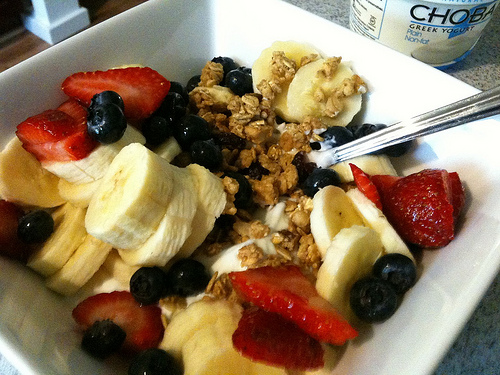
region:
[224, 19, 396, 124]
bananas with granola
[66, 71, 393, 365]
fruit plate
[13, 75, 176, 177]
strawberries bananas and blueberries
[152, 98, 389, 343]
fruit salad with cream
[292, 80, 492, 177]
hardware inside a fruit plate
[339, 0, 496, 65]
cup of yogart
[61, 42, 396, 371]
fruit plate with bananas and yogurt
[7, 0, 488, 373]
fruit salad in a to go box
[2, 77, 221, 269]
cut bananas strawberries and blueberries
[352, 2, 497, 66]
greek yugurt cup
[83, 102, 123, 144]
a blueberry in the bowl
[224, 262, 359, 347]
a strawberry slice in the bowl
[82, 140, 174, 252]
a banana slice in the bowl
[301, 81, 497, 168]
a metal eating utensil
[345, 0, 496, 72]
a cup of yogurt next to the bowl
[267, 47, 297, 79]
a cluster of brown granola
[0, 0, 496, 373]
a white bowl filled with fruit and granola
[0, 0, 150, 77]
a brown wooden floog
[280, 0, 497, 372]
a gray tile table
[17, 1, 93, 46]
a white pillar on the floor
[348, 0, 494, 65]
a container of yogurt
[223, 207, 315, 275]
granola and yogurt mixed together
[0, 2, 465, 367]
a white bowl for food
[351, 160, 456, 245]
slices of strawberries in the corner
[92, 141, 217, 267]
slices of banana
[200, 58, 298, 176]
a bunch of granola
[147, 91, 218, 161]
a bunch of blueberries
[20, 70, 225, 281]
slices of mixed fruit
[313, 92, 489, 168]
a metal spoon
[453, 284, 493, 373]
a grey counter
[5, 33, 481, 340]
granola and fruit served in a white square bowl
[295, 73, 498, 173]
a silver spoon coming out of the bowl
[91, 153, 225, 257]
three banana slices in the bowl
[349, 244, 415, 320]
two plump blueberries in the bowl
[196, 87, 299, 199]
a bunch of granola in the bowl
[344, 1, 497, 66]
a container of yogurt next to the bowl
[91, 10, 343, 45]
the edge of the white bowl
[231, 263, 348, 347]
a red juicy strawberry slice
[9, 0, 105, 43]
a white object on the table near the bowl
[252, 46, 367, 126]
two banana slices topped with granola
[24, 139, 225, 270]
Bananas are sliced thick.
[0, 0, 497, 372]
Breakfast bowl is square.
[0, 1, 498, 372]
Yogurt on the right side of bowl.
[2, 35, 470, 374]
Fresh fruit and bran cereal for Breakfast.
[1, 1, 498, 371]
The square bowl is all white.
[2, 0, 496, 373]
Spoon rests in the bowl.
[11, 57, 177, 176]
Strawberries are red and ripe.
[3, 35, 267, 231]
Three kinds of fruit in a bowl.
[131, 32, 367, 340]
Bran is crunchy and crispy.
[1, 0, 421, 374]
Bananas are ripe and sweet.